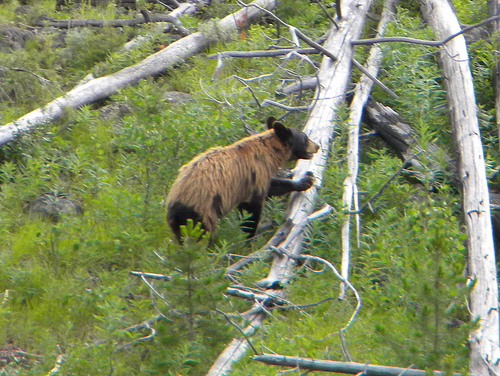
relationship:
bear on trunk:
[167, 116, 320, 250] [212, 4, 384, 374]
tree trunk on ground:
[215, 229, 345, 354] [159, 309, 198, 346]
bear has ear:
[167, 116, 320, 250] [270, 123, 295, 147]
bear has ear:
[167, 116, 320, 250] [264, 113, 280, 133]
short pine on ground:
[151, 218, 222, 365] [1, 4, 492, 374]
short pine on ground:
[390, 245, 464, 358] [1, 4, 492, 374]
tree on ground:
[401, 50, 444, 138] [1, 4, 492, 374]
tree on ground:
[32, 1, 283, 125] [1, 4, 492, 374]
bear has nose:
[167, 116, 320, 250] [309, 143, 323, 153]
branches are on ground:
[79, 245, 397, 360] [1, 4, 492, 374]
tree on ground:
[6, 17, 208, 125] [1, 4, 492, 374]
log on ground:
[443, 46, 495, 294] [1, 4, 492, 374]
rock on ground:
[28, 181, 87, 223] [403, 99, 441, 131]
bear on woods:
[167, 116, 320, 250] [0, 0, 496, 374]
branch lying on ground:
[220, 312, 470, 373] [1, 4, 492, 374]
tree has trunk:
[124, 6, 499, 213] [2, 65, 119, 148]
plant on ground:
[156, 337, 203, 374] [6, 262, 498, 374]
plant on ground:
[2, 283, 21, 322] [1, 4, 492, 374]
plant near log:
[397, 188, 461, 344] [430, 127, 496, 353]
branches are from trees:
[232, 236, 359, 350] [144, 212, 231, 372]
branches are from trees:
[232, 236, 359, 350] [370, 229, 470, 374]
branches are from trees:
[232, 236, 359, 350] [7, 116, 147, 279]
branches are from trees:
[225, 10, 327, 109] [144, 212, 231, 372]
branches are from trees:
[225, 10, 327, 109] [370, 229, 470, 374]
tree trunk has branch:
[204, 0, 374, 376] [352, 14, 499, 49]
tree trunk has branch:
[204, 0, 374, 376] [233, 2, 338, 61]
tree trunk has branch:
[417, 0, 500, 376] [233, 2, 338, 61]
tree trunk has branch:
[417, 0, 500, 376] [203, 46, 321, 66]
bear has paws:
[167, 116, 320, 250] [301, 170, 313, 187]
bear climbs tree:
[163, 118, 317, 244] [161, 2, 407, 370]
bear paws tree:
[167, 116, 320, 250] [277, 50, 363, 300]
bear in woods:
[167, 116, 320, 250] [269, 16, 479, 141]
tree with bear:
[203, 0, 499, 375] [163, 118, 317, 244]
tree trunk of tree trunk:
[420, 6, 495, 374] [357, 88, 457, 196]